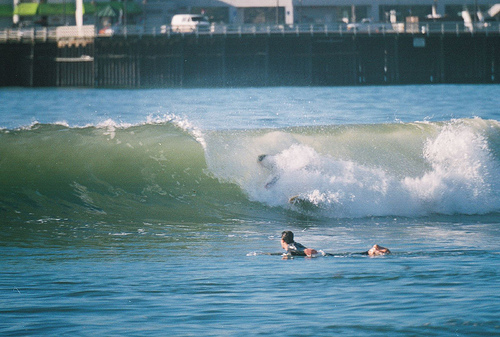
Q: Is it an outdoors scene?
A: Yes, it is outdoors.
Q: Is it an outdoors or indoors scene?
A: It is outdoors.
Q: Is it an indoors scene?
A: No, it is outdoors.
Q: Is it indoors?
A: No, it is outdoors.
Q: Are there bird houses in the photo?
A: No, there are no bird houses.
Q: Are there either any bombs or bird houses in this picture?
A: No, there are no bird houses or bombs.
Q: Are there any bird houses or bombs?
A: No, there are no bird houses or bombs.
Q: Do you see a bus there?
A: No, there are no buses.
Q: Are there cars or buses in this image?
A: No, there are no buses or cars.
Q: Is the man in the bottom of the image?
A: Yes, the man is in the bottom of the image.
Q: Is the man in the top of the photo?
A: No, the man is in the bottom of the image.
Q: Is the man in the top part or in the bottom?
A: The man is in the bottom of the image.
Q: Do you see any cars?
A: No, there are no cars.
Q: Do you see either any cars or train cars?
A: No, there are no cars or train cars.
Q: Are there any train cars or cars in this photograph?
A: No, there are no cars or train cars.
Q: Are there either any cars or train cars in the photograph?
A: No, there are no cars or train cars.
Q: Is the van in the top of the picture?
A: Yes, the van is in the top of the image.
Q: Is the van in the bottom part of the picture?
A: No, the van is in the top of the image.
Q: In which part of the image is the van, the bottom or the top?
A: The van is in the top of the image.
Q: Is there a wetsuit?
A: Yes, there is a wetsuit.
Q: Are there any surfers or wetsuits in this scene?
A: Yes, there is a wetsuit.